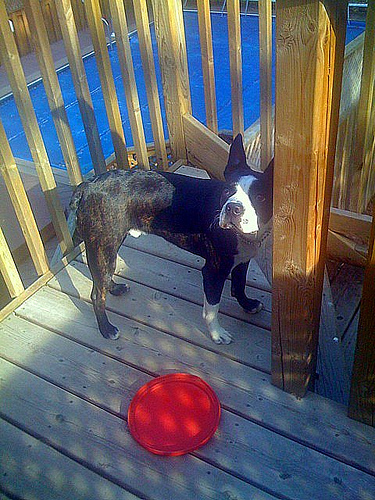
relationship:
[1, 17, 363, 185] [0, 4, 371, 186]
water in pool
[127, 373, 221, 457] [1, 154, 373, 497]
bucket top lying on ground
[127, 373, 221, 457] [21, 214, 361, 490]
bucket top lying on ground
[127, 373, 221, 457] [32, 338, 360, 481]
bucket top lying on ground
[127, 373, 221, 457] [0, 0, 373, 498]
bucket top lying on deck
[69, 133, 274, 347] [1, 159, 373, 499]
bulldog on deck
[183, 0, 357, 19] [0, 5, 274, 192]
railing in swimming pool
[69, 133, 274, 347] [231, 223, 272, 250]
bulldog wearing collar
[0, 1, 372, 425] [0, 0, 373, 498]
railing on deck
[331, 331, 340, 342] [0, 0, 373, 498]
bolt on deck